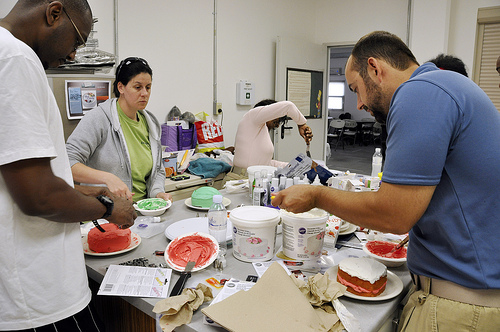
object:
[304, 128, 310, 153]
knife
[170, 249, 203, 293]
knife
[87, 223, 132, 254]
cake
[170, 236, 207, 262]
frosting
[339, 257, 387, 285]
frosting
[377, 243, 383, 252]
frosting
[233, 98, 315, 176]
woman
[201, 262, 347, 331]
paper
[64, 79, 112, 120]
small poster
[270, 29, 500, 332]
man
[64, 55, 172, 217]
lady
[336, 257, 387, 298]
cake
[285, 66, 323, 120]
bulletin board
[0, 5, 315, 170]
wall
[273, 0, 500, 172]
wall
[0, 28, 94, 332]
shirt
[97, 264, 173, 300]
paper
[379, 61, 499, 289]
blue shirt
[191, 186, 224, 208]
cake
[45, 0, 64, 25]
ear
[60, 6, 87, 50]
glasses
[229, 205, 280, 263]
bucket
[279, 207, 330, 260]
bucket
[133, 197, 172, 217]
bowl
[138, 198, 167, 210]
icing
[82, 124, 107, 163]
gray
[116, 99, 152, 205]
green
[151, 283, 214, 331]
napkin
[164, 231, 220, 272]
plate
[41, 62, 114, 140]
board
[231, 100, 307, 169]
shirt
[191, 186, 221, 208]
icing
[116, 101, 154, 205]
shirt.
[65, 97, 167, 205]
jacket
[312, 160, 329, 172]
cake